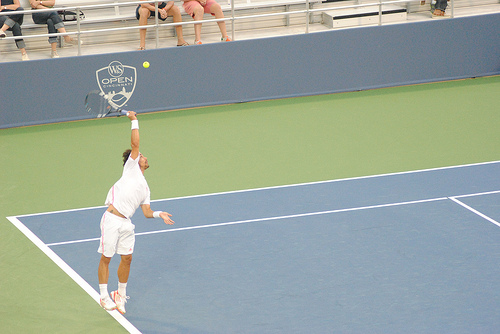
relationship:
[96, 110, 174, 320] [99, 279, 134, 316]
man wearing shoes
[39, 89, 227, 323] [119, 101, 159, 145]
player wearing wristband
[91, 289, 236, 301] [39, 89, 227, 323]
shoes on player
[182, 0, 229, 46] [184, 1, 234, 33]
person wearing shorts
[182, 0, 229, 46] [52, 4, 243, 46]
person in bleachers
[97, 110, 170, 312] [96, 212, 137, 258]
person wearing shorts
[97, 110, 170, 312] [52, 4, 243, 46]
person in bleachers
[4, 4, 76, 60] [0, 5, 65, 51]
women wearing jeans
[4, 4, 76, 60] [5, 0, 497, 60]
women in bleachers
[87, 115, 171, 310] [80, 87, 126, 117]
he swinging raquet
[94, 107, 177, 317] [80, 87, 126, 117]
he holding raquet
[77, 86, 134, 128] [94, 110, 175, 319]
tennis racket swung by tennis player